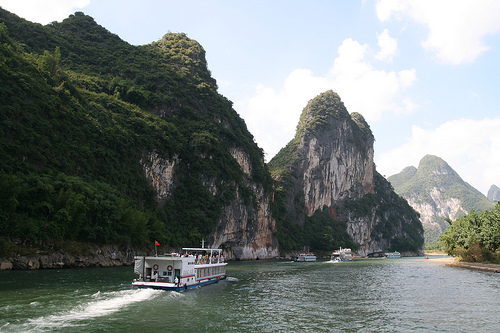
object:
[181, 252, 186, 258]
people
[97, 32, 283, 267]
mountain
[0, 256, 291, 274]
shoreline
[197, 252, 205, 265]
people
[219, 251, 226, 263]
many people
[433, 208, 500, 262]
trees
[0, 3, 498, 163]
sky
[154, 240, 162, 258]
flag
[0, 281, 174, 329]
waves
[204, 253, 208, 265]
people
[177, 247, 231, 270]
deck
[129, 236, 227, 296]
boat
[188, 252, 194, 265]
people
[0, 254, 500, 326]
water